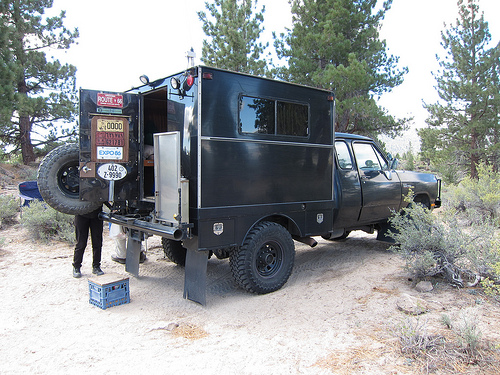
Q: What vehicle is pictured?
A: A truck.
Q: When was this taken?
A: Daytime.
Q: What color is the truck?
A: Black.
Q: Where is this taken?
A: On a dirt road.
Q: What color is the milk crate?
A: Blue.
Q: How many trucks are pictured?
A: One.